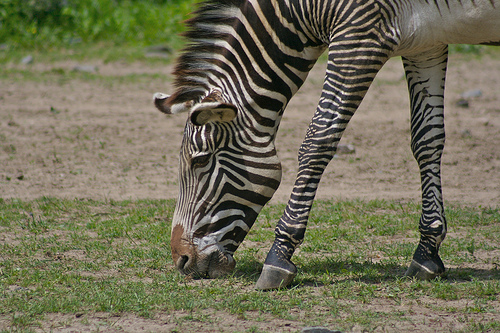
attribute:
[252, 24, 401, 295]
leg — zebra's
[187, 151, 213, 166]
eye — black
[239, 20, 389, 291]
leg — zebra's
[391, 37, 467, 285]
leg — zebra's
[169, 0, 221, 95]
mane — zebra's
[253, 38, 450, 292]
legs — all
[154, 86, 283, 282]
head — zebra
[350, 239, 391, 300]
grass — green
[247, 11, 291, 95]
pattern — striped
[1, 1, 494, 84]
grass — green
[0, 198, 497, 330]
grass — green, patchy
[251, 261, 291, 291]
hoof — zebra's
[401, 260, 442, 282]
hoof — zebra's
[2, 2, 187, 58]
bushes — in background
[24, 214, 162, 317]
grass — green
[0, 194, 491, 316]
grass — green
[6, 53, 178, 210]
ground — barren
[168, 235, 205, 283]
snout — zebra